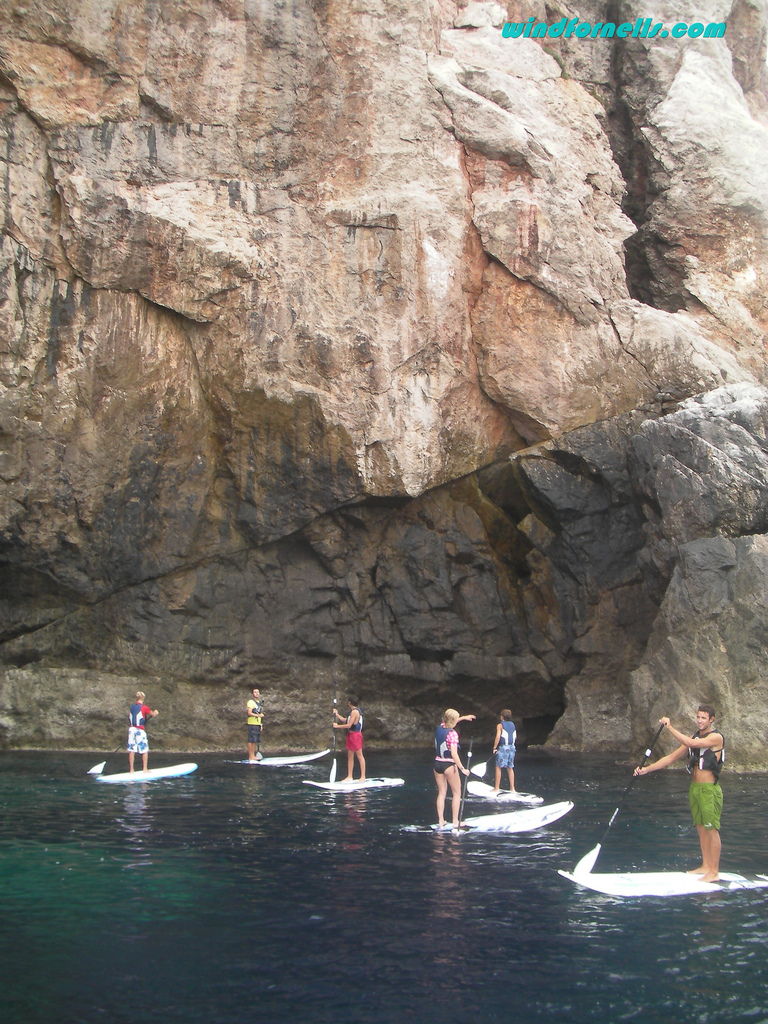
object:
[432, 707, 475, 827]
person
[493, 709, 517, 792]
person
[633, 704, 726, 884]
person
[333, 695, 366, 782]
person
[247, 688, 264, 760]
person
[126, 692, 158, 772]
person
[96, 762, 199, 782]
surfboard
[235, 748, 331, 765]
surfboard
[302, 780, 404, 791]
surfboard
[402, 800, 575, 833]
surfboard